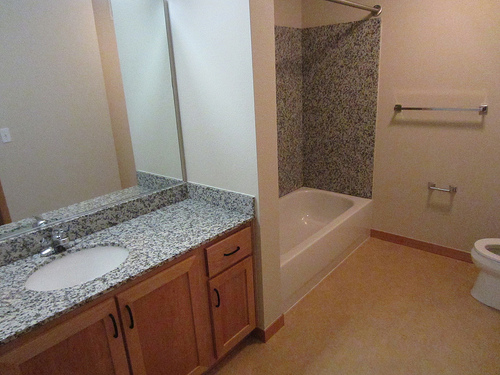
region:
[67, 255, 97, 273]
A white hand wash basin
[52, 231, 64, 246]
A metallic tap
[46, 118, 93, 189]
Mirror on the wall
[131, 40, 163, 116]
Reflecton of wall in the mirror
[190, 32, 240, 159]
A white wall surface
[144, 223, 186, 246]
A counter top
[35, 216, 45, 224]
Reflection of tap in the mirror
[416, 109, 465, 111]
Rod for hanging towel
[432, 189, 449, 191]
Toilet paper fixture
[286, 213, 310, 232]
A shower basin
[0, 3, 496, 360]
big clean bathroom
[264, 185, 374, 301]
white clean bathtub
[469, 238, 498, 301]
white clean toilet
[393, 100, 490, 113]
handle pole in wall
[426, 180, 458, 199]
pole for toilet paper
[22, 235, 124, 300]
white handwash on counter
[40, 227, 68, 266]
gray metal tap of handwash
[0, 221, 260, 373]
cabinets on brown wooden on top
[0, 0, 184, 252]
mirror in fornt of handwash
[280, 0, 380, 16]
gray metal pole for curtains of shower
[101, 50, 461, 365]
view is in a washroom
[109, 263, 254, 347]
the drawers are brown in color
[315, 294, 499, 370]
the floor is brown in color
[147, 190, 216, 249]
the surface is cemented black and white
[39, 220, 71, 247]
the tap is silvery in color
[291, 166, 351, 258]
the bathtub is white in color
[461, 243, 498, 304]
the toilet seat is white in color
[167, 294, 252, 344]
the drawers are wooden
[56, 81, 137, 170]
the mirror reflects the wall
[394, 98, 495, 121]
the handle are metallic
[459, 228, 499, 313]
a toilet in a bathroom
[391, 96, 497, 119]
a handle on a wall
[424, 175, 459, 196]
a small handle for toilet paper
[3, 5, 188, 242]
a mirror in front a counter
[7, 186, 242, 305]
a counter color salt and pepper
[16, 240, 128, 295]
the sink is white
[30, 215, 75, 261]
faucet is color silver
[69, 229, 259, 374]
counters under a sink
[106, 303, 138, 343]
black handles of counter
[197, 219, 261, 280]
a drawer under a counter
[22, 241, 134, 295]
bathroom sink is white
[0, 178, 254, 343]
granite counter top is black and white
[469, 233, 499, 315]
toilet bowl is white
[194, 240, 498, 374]
bathroom floor is carpet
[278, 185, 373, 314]
the bathtub is white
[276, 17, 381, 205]
flecked granite behind bathtub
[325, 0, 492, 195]
metal bars for bathroom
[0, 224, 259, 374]
wooden cabinets under counter top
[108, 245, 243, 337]
black handles on cabinets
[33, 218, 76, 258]
faucet handle on sink